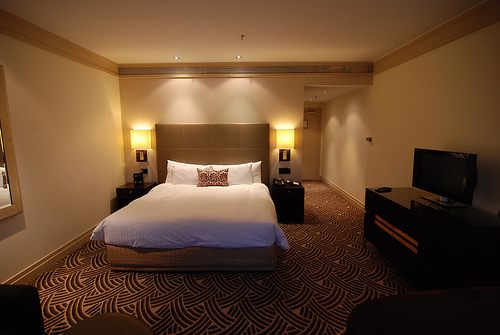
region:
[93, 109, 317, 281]
two nightstands on either side of bed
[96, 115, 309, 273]
dark brown nightstands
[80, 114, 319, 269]
two nightstands made of wood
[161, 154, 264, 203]
one decorative pillow in front of white pillows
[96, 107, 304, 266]
bed with tan headboard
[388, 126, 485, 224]
black TV is turned off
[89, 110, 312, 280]
two lamps on either side of the bed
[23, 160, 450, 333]
beige and brown patterned carpet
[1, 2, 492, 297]
cream-colored walls and ceiling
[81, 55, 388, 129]
decorative strip at the top of the wall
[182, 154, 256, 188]
the pillow is red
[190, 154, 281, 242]
the pillow is red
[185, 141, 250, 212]
the pillow is red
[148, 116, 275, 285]
A BROWN HOTEL BED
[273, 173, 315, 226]
A SIDE TABLE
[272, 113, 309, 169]
A WALL LAMP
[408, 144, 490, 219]
A TELEVISION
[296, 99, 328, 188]
HOTEL DOOR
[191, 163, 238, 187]
A BROWN PATTERN PILLOW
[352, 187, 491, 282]
A HOTEL DRESSER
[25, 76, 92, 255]
A WHITE WALL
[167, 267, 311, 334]
A BROWN AND WHITE PATTERNED HOTEL RUG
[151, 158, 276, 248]
WHITE COTTON HOTEL BEDDING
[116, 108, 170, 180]
the lampshade is on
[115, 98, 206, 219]
the lampshade is on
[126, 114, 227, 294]
the lampshade is on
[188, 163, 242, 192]
smal decorative red and gold pillow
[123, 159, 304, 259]
white comforter set on bed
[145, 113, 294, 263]
tan colored headboard and platform bed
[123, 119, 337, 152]
identical small wall lamps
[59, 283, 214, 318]
black and yellow colore carpet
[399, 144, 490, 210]
black flat screen TV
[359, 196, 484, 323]
black and gold shiny dreser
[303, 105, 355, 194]
entry way to door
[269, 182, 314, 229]
small black night stand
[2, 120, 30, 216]
yellow framed mirror